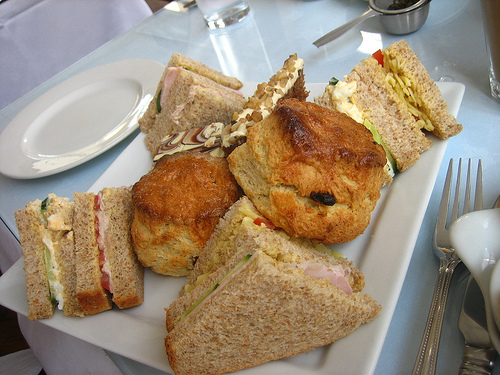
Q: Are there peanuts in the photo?
A: No, there are no peanuts.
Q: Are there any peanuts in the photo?
A: No, there are no peanuts.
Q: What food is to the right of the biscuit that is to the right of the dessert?
A: The food is a pastry.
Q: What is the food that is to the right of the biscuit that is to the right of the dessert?
A: The food is a pastry.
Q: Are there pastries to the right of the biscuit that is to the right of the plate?
A: Yes, there is a pastry to the right of the biscuit.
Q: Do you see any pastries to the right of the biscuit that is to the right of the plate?
A: Yes, there is a pastry to the right of the biscuit.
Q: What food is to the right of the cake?
A: The food is a pastry.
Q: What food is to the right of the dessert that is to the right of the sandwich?
A: The food is a pastry.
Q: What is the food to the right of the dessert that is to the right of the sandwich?
A: The food is a pastry.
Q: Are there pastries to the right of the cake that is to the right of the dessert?
A: Yes, there is a pastry to the right of the cake.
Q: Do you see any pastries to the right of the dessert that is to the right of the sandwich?
A: Yes, there is a pastry to the right of the cake.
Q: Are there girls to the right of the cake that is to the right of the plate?
A: No, there is a pastry to the right of the cake.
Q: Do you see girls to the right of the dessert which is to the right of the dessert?
A: No, there is a pastry to the right of the cake.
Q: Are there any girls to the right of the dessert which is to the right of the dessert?
A: No, there is a pastry to the right of the cake.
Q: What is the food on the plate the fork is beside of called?
A: The food is a pastry.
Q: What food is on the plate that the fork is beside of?
A: The food is a pastry.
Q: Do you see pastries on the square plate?
A: Yes, there is a pastry on the plate.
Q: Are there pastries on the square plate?
A: Yes, there is a pastry on the plate.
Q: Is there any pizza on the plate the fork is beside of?
A: No, there is a pastry on the plate.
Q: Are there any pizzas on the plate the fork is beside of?
A: No, there is a pastry on the plate.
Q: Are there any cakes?
A: Yes, there is a cake.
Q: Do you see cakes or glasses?
A: Yes, there is a cake.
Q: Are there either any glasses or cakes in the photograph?
A: Yes, there is a cake.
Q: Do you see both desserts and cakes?
A: Yes, there are both a cake and a dessert.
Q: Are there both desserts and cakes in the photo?
A: Yes, there are both a cake and a dessert.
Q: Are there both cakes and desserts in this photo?
A: Yes, there are both a cake and a dessert.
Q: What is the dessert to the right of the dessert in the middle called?
A: The dessert is a cake.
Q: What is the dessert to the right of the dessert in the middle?
A: The dessert is a cake.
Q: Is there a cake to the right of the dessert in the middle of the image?
A: Yes, there is a cake to the right of the dessert.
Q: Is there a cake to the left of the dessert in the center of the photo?
A: No, the cake is to the right of the dessert.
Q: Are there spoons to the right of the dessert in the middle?
A: No, there is a cake to the right of the dessert.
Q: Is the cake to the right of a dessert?
A: Yes, the cake is to the right of a dessert.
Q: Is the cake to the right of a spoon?
A: No, the cake is to the right of a dessert.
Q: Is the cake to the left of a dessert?
A: No, the cake is to the right of a dessert.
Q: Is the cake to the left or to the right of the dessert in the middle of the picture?
A: The cake is to the right of the dessert.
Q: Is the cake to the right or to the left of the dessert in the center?
A: The cake is to the right of the dessert.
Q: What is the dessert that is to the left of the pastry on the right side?
A: The dessert is a cake.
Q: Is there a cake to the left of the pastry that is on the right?
A: Yes, there is a cake to the left of the pastry.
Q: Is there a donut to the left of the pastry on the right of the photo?
A: No, there is a cake to the left of the pastry.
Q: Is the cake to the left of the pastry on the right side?
A: Yes, the cake is to the left of the pastry.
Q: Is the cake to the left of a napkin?
A: No, the cake is to the left of the pastry.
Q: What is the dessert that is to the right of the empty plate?
A: The dessert is a cake.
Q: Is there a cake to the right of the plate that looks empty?
A: Yes, there is a cake to the right of the plate.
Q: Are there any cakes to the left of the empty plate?
A: No, the cake is to the right of the plate.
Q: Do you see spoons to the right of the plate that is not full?
A: No, there is a cake to the right of the plate.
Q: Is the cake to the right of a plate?
A: Yes, the cake is to the right of a plate.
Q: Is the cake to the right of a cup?
A: No, the cake is to the right of a plate.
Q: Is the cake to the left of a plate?
A: No, the cake is to the right of a plate.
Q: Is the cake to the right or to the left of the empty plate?
A: The cake is to the right of the plate.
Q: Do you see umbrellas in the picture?
A: No, there are no umbrellas.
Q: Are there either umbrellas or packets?
A: No, there are no umbrellas or packets.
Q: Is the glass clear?
A: Yes, the glass is clear.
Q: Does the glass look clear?
A: Yes, the glass is clear.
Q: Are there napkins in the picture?
A: No, there are no napkins.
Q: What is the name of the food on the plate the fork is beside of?
A: The food is a biscuit.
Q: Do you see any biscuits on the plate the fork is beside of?
A: Yes, there is a biscuit on the plate.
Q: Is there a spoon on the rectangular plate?
A: No, there is a biscuit on the plate.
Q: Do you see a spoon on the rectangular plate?
A: No, there is a biscuit on the plate.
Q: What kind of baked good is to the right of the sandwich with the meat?
A: The food is a biscuit.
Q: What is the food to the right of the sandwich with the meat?
A: The food is a biscuit.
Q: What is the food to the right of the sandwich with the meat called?
A: The food is a biscuit.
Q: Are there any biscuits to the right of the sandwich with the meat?
A: Yes, there is a biscuit to the right of the sandwich.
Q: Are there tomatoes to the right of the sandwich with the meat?
A: No, there is a biscuit to the right of the sandwich.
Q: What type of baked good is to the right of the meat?
A: The food is a biscuit.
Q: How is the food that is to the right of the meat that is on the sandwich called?
A: The food is a biscuit.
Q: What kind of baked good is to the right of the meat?
A: The food is a biscuit.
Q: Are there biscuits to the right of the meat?
A: Yes, there is a biscuit to the right of the meat.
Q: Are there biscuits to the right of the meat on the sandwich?
A: Yes, there is a biscuit to the right of the meat.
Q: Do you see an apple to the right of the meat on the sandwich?
A: No, there is a biscuit to the right of the meat.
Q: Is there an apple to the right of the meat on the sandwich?
A: No, there is a biscuit to the right of the meat.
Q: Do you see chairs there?
A: No, there are no chairs.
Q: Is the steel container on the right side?
A: Yes, the container is on the right of the image.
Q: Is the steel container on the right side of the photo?
A: Yes, the container is on the right of the image.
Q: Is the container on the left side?
A: No, the container is on the right of the image.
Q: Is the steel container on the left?
A: No, the container is on the right of the image.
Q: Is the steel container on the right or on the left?
A: The container is on the right of the image.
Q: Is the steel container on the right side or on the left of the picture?
A: The container is on the right of the image.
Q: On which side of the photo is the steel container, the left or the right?
A: The container is on the right of the image.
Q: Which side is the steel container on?
A: The container is on the right of the image.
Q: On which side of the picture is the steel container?
A: The container is on the right of the image.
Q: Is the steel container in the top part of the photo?
A: Yes, the container is in the top of the image.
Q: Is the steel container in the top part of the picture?
A: Yes, the container is in the top of the image.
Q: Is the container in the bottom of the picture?
A: No, the container is in the top of the image.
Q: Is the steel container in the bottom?
A: No, the container is in the top of the image.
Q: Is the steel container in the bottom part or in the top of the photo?
A: The container is in the top of the image.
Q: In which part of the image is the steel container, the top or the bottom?
A: The container is in the top of the image.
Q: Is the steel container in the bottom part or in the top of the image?
A: The container is in the top of the image.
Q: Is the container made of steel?
A: Yes, the container is made of steel.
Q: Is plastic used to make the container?
A: No, the container is made of steel.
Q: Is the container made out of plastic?
A: No, the container is made of steel.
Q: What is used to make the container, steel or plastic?
A: The container is made of steel.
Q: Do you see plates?
A: Yes, there is a plate.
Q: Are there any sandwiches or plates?
A: Yes, there is a plate.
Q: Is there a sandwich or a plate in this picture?
A: Yes, there is a plate.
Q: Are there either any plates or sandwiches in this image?
A: Yes, there is a plate.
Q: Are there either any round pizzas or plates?
A: Yes, there is a round plate.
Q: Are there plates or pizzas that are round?
A: Yes, the plate is round.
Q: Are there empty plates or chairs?
A: Yes, there is an empty plate.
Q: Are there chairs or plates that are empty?
A: Yes, the plate is empty.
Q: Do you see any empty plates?
A: Yes, there is an empty plate.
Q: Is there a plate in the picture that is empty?
A: Yes, there is a plate that is empty.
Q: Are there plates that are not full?
A: Yes, there is a empty plate.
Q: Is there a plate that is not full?
A: Yes, there is a empty plate.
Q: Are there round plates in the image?
A: Yes, there is a round plate.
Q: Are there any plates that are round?
A: Yes, there is a plate that is round.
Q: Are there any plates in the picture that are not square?
A: Yes, there is a round plate.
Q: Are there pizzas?
A: No, there are no pizzas.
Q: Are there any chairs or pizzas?
A: No, there are no pizzas or chairs.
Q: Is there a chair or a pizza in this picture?
A: No, there are no pizzas or chairs.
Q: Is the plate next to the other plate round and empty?
A: Yes, the plate is round and empty.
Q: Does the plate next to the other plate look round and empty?
A: Yes, the plate is round and empty.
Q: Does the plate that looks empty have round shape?
A: Yes, the plate is round.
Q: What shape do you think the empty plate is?
A: The plate is round.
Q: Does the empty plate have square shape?
A: No, the plate is round.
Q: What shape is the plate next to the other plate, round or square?
A: The plate is round.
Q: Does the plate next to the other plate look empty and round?
A: Yes, the plate is empty and round.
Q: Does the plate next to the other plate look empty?
A: Yes, the plate is empty.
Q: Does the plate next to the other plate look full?
A: No, the plate is empty.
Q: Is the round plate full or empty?
A: The plate is empty.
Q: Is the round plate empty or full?
A: The plate is empty.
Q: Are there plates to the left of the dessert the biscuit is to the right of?
A: Yes, there is a plate to the left of the dessert.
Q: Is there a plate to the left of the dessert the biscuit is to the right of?
A: Yes, there is a plate to the left of the dessert.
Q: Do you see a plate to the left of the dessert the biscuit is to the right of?
A: Yes, there is a plate to the left of the dessert.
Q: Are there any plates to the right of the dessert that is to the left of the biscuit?
A: No, the plate is to the left of the dessert.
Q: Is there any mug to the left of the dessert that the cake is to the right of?
A: No, there is a plate to the left of the dessert.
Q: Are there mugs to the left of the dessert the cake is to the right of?
A: No, there is a plate to the left of the dessert.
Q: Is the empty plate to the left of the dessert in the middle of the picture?
A: Yes, the plate is to the left of the dessert.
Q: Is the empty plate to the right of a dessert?
A: No, the plate is to the left of a dessert.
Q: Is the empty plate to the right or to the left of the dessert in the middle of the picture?
A: The plate is to the left of the dessert.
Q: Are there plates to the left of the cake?
A: Yes, there is a plate to the left of the cake.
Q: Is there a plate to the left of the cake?
A: Yes, there is a plate to the left of the cake.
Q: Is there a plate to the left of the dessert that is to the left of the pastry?
A: Yes, there is a plate to the left of the cake.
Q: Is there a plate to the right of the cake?
A: No, the plate is to the left of the cake.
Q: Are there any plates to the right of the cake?
A: No, the plate is to the left of the cake.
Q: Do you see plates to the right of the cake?
A: No, the plate is to the left of the cake.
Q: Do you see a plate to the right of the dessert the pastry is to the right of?
A: No, the plate is to the left of the cake.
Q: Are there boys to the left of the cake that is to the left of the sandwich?
A: No, there is a plate to the left of the cake.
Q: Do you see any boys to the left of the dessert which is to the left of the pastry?
A: No, there is a plate to the left of the cake.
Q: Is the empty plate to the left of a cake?
A: Yes, the plate is to the left of a cake.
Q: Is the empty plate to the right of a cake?
A: No, the plate is to the left of a cake.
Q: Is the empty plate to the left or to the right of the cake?
A: The plate is to the left of the cake.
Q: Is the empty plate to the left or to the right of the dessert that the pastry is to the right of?
A: The plate is to the left of the cake.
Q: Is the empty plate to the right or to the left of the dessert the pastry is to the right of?
A: The plate is to the left of the cake.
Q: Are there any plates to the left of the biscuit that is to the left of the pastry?
A: Yes, there is a plate to the left of the biscuit.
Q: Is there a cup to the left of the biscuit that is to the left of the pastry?
A: No, there is a plate to the left of the biscuit.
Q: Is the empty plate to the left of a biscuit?
A: Yes, the plate is to the left of a biscuit.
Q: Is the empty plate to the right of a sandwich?
A: No, the plate is to the left of a sandwich.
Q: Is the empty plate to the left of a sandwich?
A: Yes, the plate is to the left of a sandwich.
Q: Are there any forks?
A: Yes, there is a fork.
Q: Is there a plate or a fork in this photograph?
A: Yes, there is a fork.